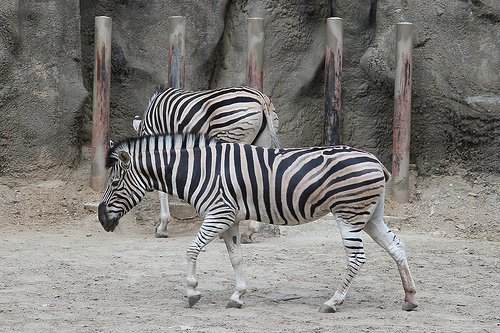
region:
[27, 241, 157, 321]
The ground is the color brown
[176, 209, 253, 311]
The front legs of the zebra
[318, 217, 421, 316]
The back legs of the zebra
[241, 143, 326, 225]
The stomach of the zebra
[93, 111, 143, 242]
The head of the zebra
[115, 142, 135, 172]
The ear of the zebra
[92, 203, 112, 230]
The nose of the zebra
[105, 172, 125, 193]
The eye of the zebra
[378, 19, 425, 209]
The pole in the ground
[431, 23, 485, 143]
The wall is made of rock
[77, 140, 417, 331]
the zebra is walking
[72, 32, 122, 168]
a gray and rusty pole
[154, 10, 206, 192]
a gray and rusty pole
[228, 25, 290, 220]
a gray and rusty pole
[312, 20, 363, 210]
a gray and rusty pole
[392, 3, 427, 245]
a gray and rusty pole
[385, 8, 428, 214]
metal post against the rocks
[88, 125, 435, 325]
zebra in an enclosure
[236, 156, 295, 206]
stripes on a zebra's side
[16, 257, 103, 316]
dirt ground in the enclosure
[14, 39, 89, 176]
rock wall behind the zebras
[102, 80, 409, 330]
two zebras in an enclosure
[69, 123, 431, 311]
zebra walking in front of the camera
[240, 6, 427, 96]
metal posts against a stone wall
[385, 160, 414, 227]
metal post in the ground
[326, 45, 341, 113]
paint missing on the post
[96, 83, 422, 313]
zebra walking in front of another zebra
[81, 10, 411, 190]
line of grey poles in back of zebras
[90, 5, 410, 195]
poles with black and red markings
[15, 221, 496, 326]
flat and dry gray ground with pebbles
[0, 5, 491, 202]
overlapping gray boulders in back of poles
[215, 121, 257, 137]
thin and wavy lines on rear of zebra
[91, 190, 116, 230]
black nose and mouth on edge of head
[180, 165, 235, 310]
pointed foreleg of moving zebra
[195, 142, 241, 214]
vertical lines dividing at base of leg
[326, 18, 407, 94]
pointy rock tip between poles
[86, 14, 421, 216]
The pipes behind the zebras.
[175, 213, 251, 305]
The front legs of the zebra that is fully visible.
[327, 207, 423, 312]
The back legs of the zebra that is fully visible.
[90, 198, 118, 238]
The nose and mouth of the zebra that is fully visible.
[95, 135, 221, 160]
The mane on the zebra that is fully visible.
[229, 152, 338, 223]
The stripes in the stomach area on the zebra that is fully visible.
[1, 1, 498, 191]
The gray wall behind the poles.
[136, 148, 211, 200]
The stripes on the zebra's neck that is fully visible.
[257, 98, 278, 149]
The tail of the zebra closest to the wall.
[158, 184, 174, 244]
The leg of the zebra closest to the wall.